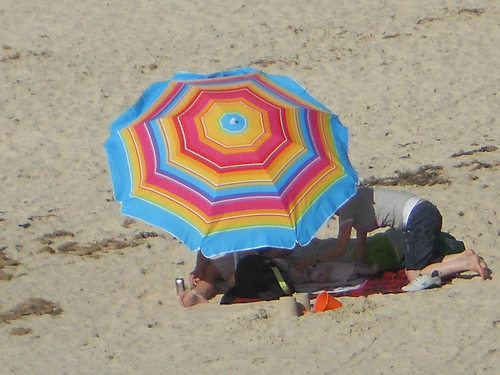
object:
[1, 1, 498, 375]
ground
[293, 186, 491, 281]
person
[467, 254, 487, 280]
foot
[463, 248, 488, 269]
foot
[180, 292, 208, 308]
foot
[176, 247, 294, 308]
person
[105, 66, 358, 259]
umbrella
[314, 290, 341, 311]
bucket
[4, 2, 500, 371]
beach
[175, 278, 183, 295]
can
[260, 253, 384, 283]
baby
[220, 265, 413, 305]
blanket